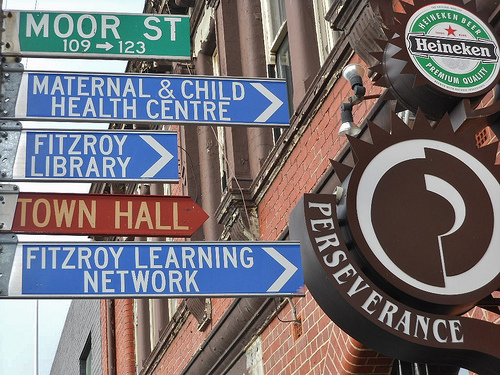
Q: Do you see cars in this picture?
A: No, there are no cars.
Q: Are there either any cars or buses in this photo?
A: No, there are no cars or buses.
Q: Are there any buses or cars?
A: No, there are no cars or buses.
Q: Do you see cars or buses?
A: No, there are no cars or buses.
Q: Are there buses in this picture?
A: No, there are no buses.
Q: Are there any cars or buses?
A: No, there are no buses or cars.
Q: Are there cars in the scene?
A: No, there are no cars.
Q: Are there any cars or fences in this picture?
A: No, there are no cars or fences.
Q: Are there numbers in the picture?
A: Yes, there are numbers.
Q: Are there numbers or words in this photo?
A: Yes, there are numbers.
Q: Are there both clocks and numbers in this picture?
A: No, there are numbers but no clocks.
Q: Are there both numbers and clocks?
A: No, there are numbers but no clocks.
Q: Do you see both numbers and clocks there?
A: No, there are numbers but no clocks.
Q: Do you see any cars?
A: No, there are no cars.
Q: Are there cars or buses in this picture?
A: No, there are no cars or buses.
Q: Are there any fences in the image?
A: No, there are no fences.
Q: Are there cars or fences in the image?
A: No, there are no fences or cars.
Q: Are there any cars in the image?
A: No, there are no cars.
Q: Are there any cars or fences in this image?
A: No, there are no cars or fences.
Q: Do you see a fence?
A: No, there are no fences.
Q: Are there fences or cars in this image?
A: No, there are no fences or cars.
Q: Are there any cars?
A: No, there are no cars.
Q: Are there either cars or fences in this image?
A: No, there are no cars or fences.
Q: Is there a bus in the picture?
A: No, there are no buses.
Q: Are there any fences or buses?
A: No, there are no buses or fences.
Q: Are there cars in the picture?
A: No, there are no cars.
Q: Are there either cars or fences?
A: No, there are no cars or fences.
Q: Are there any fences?
A: No, there are no fences.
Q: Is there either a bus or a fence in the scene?
A: No, there are no fences or buses.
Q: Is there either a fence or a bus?
A: No, there are no fences or buses.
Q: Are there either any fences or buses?
A: No, there are no fences or buses.